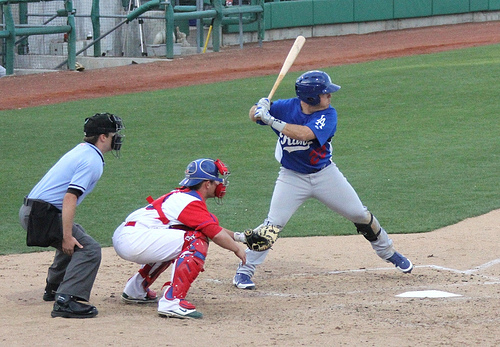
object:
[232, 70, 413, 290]
batter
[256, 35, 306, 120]
bat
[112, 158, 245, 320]
catcher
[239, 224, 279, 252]
glove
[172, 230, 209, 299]
kneepad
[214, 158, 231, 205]
mask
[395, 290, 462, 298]
home plate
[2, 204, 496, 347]
dirt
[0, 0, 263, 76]
fence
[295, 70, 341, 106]
helmet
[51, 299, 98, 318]
shoe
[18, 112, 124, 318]
empire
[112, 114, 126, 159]
mask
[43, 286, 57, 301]
shoes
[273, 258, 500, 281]
line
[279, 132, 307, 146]
team name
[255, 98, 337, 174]
jersey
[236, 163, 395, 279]
pants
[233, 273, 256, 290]
shoes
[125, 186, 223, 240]
shirt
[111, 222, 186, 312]
pants